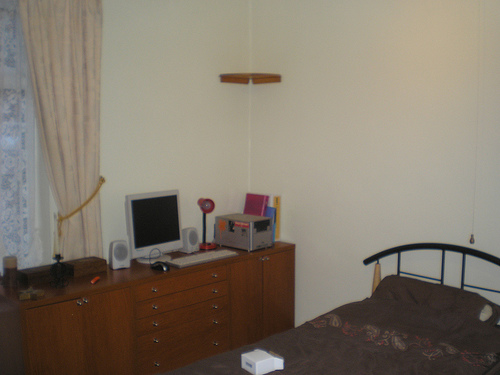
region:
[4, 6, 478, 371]
bedroom area with dresser and bed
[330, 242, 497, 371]
bed with brown flower bed spread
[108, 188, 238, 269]
computer on desk next to bed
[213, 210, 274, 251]
old cassette player on dresser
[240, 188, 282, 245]
books behind cassette recorder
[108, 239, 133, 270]
speacker for computer on dresser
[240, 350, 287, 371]
cardboard box on bed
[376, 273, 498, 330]
pillow on bed next to headbaord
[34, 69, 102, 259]
curtains next to window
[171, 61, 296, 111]
shelf in the corner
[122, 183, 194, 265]
computer monitor against the wall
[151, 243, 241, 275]
computer keyboard on the dresser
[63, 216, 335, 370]
dresser against the wall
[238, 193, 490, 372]
bed in the bedroom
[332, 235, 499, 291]
head board of the bed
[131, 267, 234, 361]
knobs on the dresser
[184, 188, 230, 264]
light on the dresser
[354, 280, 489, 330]
pillow on the bed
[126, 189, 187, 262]
computer monitor is off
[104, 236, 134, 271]
rectangular shaped computer speaker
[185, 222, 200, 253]
rectangular shaped computer speaker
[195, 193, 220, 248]
red table lamp is off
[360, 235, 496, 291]
black arched bed frame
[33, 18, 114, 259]
white satin window curtain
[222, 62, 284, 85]
brown corner wall shelf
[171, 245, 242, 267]
white computer keyboard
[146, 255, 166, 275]
black and silver computer dance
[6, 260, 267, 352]
wooden brown dresser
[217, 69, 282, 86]
the shelf in the corner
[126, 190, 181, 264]
the computer monitor on the dresser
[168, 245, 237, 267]
the keyboard on the dresser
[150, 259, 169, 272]
the mouse on the dresser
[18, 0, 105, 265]
the curtain hanging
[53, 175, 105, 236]
the chord on the curtain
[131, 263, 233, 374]
the drawers on the cabinet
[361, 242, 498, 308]
the headboard near the wall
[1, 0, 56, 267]
the lace curtain on the window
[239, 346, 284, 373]
the white box on the bed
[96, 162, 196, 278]
Computer screen on the dresser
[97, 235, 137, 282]
Speaker beside the computer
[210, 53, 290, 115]
Shelf in the corner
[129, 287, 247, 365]
Knobs on dresser drawers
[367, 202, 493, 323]
Headboard on the bed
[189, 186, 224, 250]
Lamp on the dresser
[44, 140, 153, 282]
Curtain tie back on curtain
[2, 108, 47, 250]
Window on the wall of room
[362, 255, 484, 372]
Pillow on the bed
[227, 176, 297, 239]
Two folders on the dresser